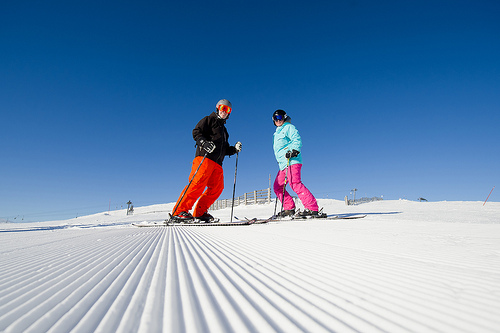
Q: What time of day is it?
A: Daytime.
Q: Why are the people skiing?
A: They are doing it for fun.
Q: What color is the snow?
A: White.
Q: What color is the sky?
A: Blue.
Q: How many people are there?
A: Two.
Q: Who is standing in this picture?
A: Women.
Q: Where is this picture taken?
A: On a ski slope.